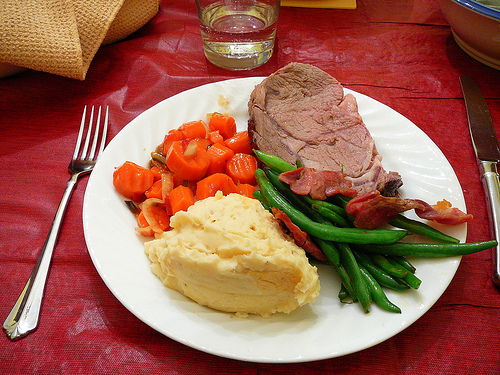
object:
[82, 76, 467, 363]
plate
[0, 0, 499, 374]
table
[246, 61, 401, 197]
meat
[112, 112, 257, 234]
carrot